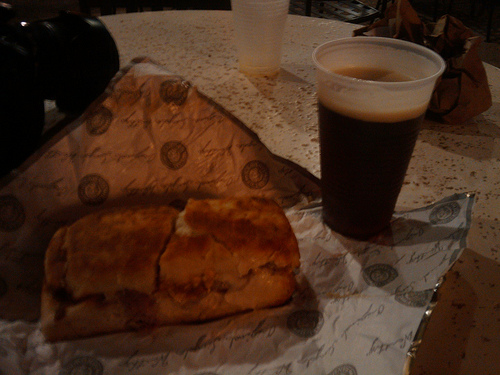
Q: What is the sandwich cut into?
A: Halves.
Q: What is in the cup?
A: Ale.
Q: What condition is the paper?
A: Wrinkled.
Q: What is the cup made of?
A: Plastic.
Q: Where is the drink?
A: In the cup.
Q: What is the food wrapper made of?
A: Aluminum.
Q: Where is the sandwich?
A: On the food wrapper.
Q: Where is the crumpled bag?
A: On the table.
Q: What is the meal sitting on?
A: A table.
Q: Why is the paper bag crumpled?
A: It's ready to be thrown away.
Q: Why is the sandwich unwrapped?
A: So it can be eaten.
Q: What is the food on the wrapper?
A: A sandwich.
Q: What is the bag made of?
A: Paper.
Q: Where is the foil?
A: Under the food.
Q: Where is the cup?
A: On the foil.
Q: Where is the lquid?
A: In the cup.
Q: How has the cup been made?
A: With plastic.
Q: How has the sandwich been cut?
A: In half.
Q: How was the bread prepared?
A: Baked.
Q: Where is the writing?
A: On the foil.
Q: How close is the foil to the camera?
A: It's touching.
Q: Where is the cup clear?
A: The top.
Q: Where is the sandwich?
A: On foil backed paper.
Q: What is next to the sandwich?
A: A drink.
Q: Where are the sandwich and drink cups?
A: On a white table.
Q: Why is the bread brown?
A: The bread was toasted.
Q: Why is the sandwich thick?
A: Because the bread is thick.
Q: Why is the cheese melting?
A: Because the sandwich was toasted.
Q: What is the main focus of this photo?
A: Food and drink.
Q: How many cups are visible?
A: Two.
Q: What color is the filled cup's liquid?
A: Brown.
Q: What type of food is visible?
A: A sandwich.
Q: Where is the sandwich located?
A: On it's wrapped.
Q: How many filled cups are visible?
A: One.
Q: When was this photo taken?
A: Outside, during night time.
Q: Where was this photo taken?
A: During a mealtime.